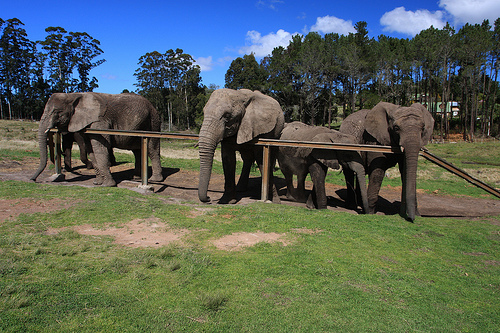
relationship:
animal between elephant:
[275, 117, 375, 212] [171, 79, 294, 226]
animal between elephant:
[275, 117, 375, 212] [330, 100, 439, 214]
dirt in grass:
[47, 212, 189, 247] [0, 134, 483, 330]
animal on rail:
[275, 117, 375, 212] [314, 141, 339, 153]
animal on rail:
[336, 100, 439, 224] [314, 141, 339, 153]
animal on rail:
[190, 87, 285, 205] [314, 141, 339, 153]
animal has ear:
[190, 87, 285, 205] [244, 82, 289, 147]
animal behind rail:
[190, 87, 285, 205] [240, 141, 376, 184]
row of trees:
[183, 50, 435, 133] [266, 22, 415, 96]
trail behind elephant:
[5, 148, 498, 222] [50, 128, 115, 168]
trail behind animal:
[5, 148, 498, 222] [30, 92, 165, 189]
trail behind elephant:
[5, 148, 498, 222] [197, 81, 281, 204]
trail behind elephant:
[5, 148, 498, 222] [275, 119, 370, 214]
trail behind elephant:
[5, 148, 498, 222] [339, 100, 435, 221]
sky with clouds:
[2, 2, 498, 87] [249, 36, 290, 52]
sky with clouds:
[2, 2, 498, 87] [381, 1, 438, 30]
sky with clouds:
[2, 2, 498, 87] [189, 52, 210, 67]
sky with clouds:
[2, 2, 498, 87] [309, 11, 353, 31]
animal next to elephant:
[190, 87, 285, 205] [39, 100, 156, 180]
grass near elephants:
[20, 191, 400, 315] [45, 82, 435, 214]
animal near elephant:
[30, 92, 165, 189] [199, 85, 268, 203]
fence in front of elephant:
[156, 142, 495, 211] [205, 89, 276, 171]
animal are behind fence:
[336, 100, 439, 224] [36, 119, 432, 216]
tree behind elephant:
[132, 45, 203, 136] [205, 88, 283, 198]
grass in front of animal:
[20, 191, 400, 315] [190, 87, 285, 205]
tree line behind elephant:
[225, 15, 491, 134] [195, 90, 279, 207]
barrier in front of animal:
[60, 110, 475, 212] [190, 87, 285, 205]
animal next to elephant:
[30, 92, 165, 189] [204, 87, 273, 214]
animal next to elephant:
[190, 87, 285, 205] [277, 113, 365, 213]